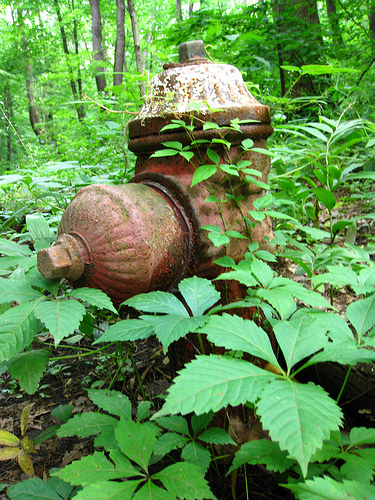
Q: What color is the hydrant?
A: Red.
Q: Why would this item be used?
A: To put out a fire.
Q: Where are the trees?
A: Behind the hydrant.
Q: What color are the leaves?
A: Green.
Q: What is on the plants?
A: Leaves.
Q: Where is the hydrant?
A: In the forest.